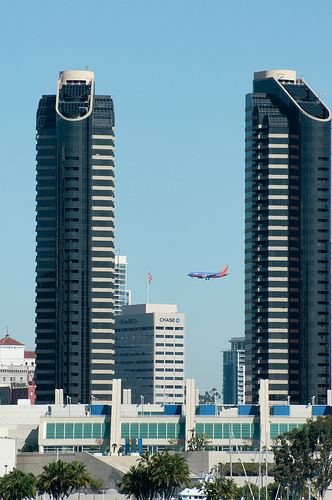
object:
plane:
[177, 263, 239, 291]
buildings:
[115, 254, 186, 402]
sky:
[0, 3, 332, 403]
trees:
[271, 412, 331, 500]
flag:
[146, 269, 156, 287]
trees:
[115, 447, 194, 498]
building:
[243, 69, 329, 409]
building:
[30, 69, 115, 406]